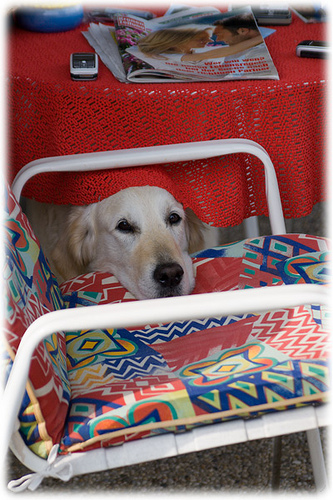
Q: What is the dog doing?
A: Sitting.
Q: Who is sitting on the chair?
A: No one.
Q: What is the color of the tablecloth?
A: Red.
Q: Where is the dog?
A: Under the table.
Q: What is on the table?
A: Phones and magazine.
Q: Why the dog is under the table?
A: Resting.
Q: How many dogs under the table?
A: One.